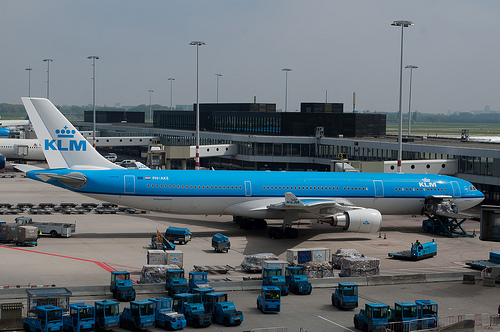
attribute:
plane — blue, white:
[13, 95, 485, 240]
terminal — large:
[0, 102, 498, 207]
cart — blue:
[23, 304, 66, 330]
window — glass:
[256, 141, 266, 158]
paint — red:
[2, 244, 143, 286]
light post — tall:
[25, 66, 36, 96]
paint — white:
[313, 314, 357, 331]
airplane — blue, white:
[14, 97, 484, 241]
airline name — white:
[416, 180, 440, 190]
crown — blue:
[54, 124, 80, 141]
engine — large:
[328, 209, 382, 232]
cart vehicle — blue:
[65, 302, 97, 331]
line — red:
[1, 243, 97, 266]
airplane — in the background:
[1, 123, 48, 165]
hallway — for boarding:
[88, 135, 160, 147]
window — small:
[145, 181, 152, 191]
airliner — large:
[12, 96, 489, 238]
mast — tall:
[195, 44, 202, 170]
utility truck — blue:
[122, 296, 157, 330]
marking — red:
[1, 243, 96, 266]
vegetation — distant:
[386, 113, 499, 138]